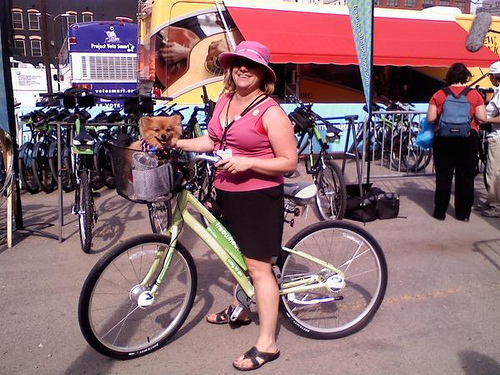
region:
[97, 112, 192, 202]
Dog in a basket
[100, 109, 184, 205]
Brown dog in a basket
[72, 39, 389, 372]
Woman riding a bicycle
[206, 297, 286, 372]
Woman is wearing sandals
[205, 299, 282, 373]
Woman is wearing black sandals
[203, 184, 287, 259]
Woman is wearing a skirt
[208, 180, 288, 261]
Woman is wearing a black skirt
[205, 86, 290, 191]
Woman is wearing a pink shirt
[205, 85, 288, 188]
Woman is wearing a shirt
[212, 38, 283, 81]
Woman is wearing a hat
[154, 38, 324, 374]
Woman is in the foreground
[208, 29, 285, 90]
Woman is wearing a pink hat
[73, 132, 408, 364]
Woman is on a bike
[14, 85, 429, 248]
Parked bikes in the background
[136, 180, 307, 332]
Bike in the foreground is light green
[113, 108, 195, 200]
A dog is in the basket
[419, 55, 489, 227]
Person in the background is wearing a backpack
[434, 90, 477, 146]
Backpack is blue in color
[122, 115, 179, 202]
a light brown Pomeranian in a bicycle basket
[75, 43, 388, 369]
lady with yellow bicycle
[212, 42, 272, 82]
a pink hat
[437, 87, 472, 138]
a blue bookbag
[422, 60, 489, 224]
a lady wearing a bookbag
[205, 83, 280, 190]
a pink sleeveless shirt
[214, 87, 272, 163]
a black lanyard with white tag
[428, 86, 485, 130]
a red short sleeve shirt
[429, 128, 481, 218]
a pair of black pants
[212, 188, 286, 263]
a pair of black shorts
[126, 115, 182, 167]
An orange pomeranian.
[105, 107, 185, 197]
A dog in a basket.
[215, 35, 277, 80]
A round pink hat.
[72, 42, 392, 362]
A woman on a bicycle.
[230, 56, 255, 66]
A pair of sunglasses.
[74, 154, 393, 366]
A light green framed bicycle.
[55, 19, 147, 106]
A purple and white bus.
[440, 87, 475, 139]
A blue backpack with black straps.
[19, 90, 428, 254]
Bicycles lined up.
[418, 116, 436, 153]
A blue plastic bag.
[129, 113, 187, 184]
A small brown dog in the bicycle basket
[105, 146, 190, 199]
A small black basket on the bicycle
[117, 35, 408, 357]
A woman riding a bike with her dog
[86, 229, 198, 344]
A thin black tire on the bike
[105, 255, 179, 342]
Thin metal spokes on the tire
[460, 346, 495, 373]
A small black shadow on the ground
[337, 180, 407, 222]
A large black bag on the ground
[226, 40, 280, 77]
A pink hat on the woman's head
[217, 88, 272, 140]
A black lanyard around the woman's neck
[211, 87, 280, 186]
The woman wears a pink shirt